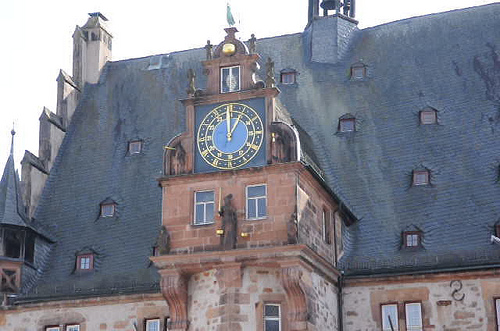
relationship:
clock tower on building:
[156, 32, 309, 328] [9, 7, 479, 326]